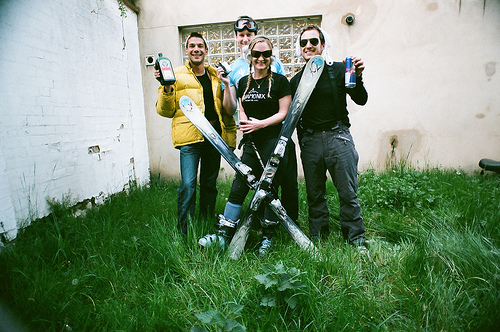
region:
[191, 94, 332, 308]
2 skis in front of people.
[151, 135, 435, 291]
People standing in long grass.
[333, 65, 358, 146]
Person holding red bull.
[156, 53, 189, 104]
Person holding bottle of jagermeister.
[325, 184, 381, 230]
Person wearing gray pants.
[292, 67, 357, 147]
Person wearing black shirt.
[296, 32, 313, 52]
Sunglasses on man's face.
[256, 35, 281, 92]
Sunglasses on woman's face.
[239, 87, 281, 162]
Woman wearing black t-shirt.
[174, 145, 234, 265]
Man wearing blue jeans.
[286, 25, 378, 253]
man holding can of red bull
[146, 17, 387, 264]
four people posing with skis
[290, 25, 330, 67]
man wearing black sunglasses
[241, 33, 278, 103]
woman wearing black sunglasses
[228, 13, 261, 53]
man wearing ski goggles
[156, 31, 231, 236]
man in yellow ski jacket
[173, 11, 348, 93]
white pane glass window behind people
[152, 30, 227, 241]
man holding green bottle with red and white label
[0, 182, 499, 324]
large green grassy area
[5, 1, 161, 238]
white brick wall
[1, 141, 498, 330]
Green grass on the ground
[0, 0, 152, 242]
White brick wall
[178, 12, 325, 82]
Window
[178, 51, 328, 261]
Pair of skis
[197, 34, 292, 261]
Woman with braided hair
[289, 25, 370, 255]
Man wearing sunglasses and holding a Red Bull energy drink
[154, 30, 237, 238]
Man wearing a yellow jacket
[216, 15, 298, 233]
Man wearing a light blue shirt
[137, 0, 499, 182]
Wall with a window in it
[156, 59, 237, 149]
A yellow jacket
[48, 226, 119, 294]
this is the grass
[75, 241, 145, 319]
the grass is green in color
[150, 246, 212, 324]
the grass is tall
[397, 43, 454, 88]
this is the wall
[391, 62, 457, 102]
the wall is white in color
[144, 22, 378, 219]
these are four people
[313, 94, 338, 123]
the sweater is black in color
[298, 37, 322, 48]
this is a pair of sunglasses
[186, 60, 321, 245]
this is a propeller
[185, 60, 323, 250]
the propeller is big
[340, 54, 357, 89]
a can of energy drink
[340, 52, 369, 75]
the hand of a man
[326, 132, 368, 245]
the leg of a man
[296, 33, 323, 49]
a pair of sunglasses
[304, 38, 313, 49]
the nose of a man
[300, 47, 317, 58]
the mouth of a man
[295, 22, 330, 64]
the head of a man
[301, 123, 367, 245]
a gray pair of pants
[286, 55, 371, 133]
a black shirt on the man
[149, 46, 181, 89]
a bottle of liquor